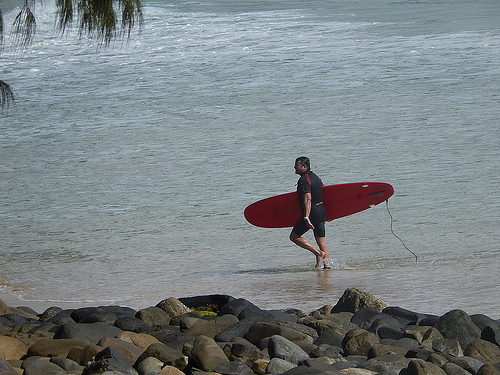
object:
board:
[242, 181, 395, 228]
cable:
[385, 198, 418, 261]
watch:
[302, 217, 309, 220]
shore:
[1, 292, 497, 372]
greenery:
[0, 0, 143, 109]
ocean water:
[0, 1, 497, 318]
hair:
[296, 156, 311, 167]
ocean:
[122, 86, 154, 120]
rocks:
[2, 293, 494, 371]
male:
[289, 156, 331, 271]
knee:
[289, 231, 302, 241]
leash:
[385, 198, 417, 262]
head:
[293, 156, 311, 174]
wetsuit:
[292, 171, 326, 237]